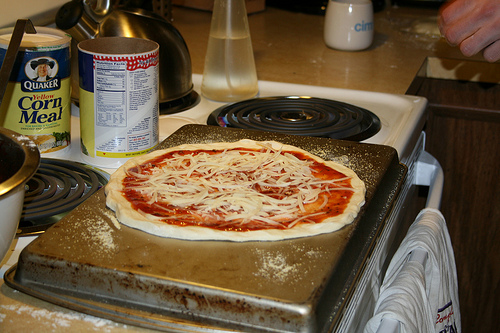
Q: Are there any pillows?
A: No, there are no pillows.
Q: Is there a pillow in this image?
A: No, there are no pillows.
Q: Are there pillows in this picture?
A: No, there are no pillows.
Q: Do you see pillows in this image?
A: No, there are no pillows.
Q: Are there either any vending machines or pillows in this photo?
A: No, there are no pillows or vending machines.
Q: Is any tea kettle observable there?
A: Yes, there is a tea kettle.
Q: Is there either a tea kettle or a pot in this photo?
A: Yes, there is a tea kettle.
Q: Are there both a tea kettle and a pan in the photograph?
A: Yes, there are both a tea kettle and a pan.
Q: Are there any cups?
A: No, there are no cups.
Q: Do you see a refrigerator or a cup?
A: No, there are no cups or refrigerators.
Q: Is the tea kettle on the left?
A: Yes, the tea kettle is on the left of the image.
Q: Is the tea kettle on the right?
A: No, the tea kettle is on the left of the image.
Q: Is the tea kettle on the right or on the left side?
A: The tea kettle is on the left of the image.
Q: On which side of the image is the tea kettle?
A: The tea kettle is on the left of the image.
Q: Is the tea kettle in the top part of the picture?
A: Yes, the tea kettle is in the top of the image.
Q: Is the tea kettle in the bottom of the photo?
A: No, the tea kettle is in the top of the image.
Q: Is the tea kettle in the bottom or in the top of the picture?
A: The tea kettle is in the top of the image.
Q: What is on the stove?
A: The tea kettle is on the stove.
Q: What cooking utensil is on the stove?
A: The cooking utensil is a tea kettle.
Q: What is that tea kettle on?
A: The tea kettle is on the stove.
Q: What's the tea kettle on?
A: The tea kettle is on the stove.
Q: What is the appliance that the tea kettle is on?
A: The appliance is a stove.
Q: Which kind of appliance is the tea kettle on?
A: The tea kettle is on the stove.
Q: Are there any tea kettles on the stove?
A: Yes, there is a tea kettle on the stove.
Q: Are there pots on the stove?
A: No, there is a tea kettle on the stove.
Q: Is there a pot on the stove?
A: No, there is a tea kettle on the stove.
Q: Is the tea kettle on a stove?
A: Yes, the tea kettle is on a stove.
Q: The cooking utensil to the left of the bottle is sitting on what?
A: The tea kettle is sitting on the stove top.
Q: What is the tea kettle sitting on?
A: The tea kettle is sitting on the stove top.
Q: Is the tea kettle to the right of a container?
A: Yes, the tea kettle is to the right of a container.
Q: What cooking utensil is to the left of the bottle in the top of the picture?
A: The cooking utensil is a tea kettle.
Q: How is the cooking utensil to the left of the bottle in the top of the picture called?
A: The cooking utensil is a tea kettle.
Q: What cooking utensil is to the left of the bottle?
A: The cooking utensil is a tea kettle.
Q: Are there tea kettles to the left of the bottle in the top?
A: Yes, there is a tea kettle to the left of the bottle.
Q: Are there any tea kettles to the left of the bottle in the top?
A: Yes, there is a tea kettle to the left of the bottle.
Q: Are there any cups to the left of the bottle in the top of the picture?
A: No, there is a tea kettle to the left of the bottle.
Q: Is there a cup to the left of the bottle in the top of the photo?
A: No, there is a tea kettle to the left of the bottle.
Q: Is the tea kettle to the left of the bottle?
A: Yes, the tea kettle is to the left of the bottle.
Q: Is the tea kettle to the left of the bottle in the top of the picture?
A: Yes, the tea kettle is to the left of the bottle.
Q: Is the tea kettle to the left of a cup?
A: No, the tea kettle is to the left of the bottle.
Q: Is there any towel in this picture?
A: Yes, there is a towel.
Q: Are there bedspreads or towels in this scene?
A: Yes, there is a towel.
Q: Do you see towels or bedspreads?
A: Yes, there is a towel.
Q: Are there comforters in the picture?
A: No, there are no comforters.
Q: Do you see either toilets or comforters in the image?
A: No, there are no comforters or toilets.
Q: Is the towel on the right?
A: Yes, the towel is on the right of the image.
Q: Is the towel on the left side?
A: No, the towel is on the right of the image.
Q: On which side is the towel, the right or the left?
A: The towel is on the right of the image.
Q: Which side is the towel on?
A: The towel is on the right of the image.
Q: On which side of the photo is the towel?
A: The towel is on the right of the image.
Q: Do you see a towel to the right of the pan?
A: Yes, there is a towel to the right of the pan.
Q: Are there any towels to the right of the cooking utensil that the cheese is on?
A: Yes, there is a towel to the right of the pan.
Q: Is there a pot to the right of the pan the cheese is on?
A: No, there is a towel to the right of the pan.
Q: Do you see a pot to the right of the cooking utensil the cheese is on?
A: No, there is a towel to the right of the pan.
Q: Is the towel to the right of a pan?
A: Yes, the towel is to the right of a pan.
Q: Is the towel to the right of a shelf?
A: No, the towel is to the right of a pan.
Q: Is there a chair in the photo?
A: No, there are no chairs.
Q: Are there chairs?
A: No, there are no chairs.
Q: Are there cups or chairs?
A: No, there are no chairs or cups.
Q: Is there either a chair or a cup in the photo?
A: No, there are no chairs or cups.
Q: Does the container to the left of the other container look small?
A: Yes, the container is small.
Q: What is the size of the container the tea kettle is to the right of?
A: The container is small.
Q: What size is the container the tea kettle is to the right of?
A: The container is small.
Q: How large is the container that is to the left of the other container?
A: The container is small.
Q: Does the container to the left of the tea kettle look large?
A: No, the container is small.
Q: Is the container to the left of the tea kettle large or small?
A: The container is small.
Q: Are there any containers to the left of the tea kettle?
A: Yes, there is a container to the left of the tea kettle.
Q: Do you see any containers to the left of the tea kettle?
A: Yes, there is a container to the left of the tea kettle.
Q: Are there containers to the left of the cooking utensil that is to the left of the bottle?
A: Yes, there is a container to the left of the tea kettle.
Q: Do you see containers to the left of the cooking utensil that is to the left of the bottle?
A: Yes, there is a container to the left of the tea kettle.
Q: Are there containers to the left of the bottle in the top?
A: Yes, there is a container to the left of the bottle.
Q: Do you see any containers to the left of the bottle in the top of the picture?
A: Yes, there is a container to the left of the bottle.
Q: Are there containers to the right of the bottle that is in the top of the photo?
A: No, the container is to the left of the bottle.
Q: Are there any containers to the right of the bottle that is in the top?
A: No, the container is to the left of the bottle.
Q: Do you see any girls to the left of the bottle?
A: No, there is a container to the left of the bottle.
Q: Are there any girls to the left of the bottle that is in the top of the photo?
A: No, there is a container to the left of the bottle.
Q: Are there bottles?
A: Yes, there is a bottle.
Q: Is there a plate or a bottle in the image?
A: Yes, there is a bottle.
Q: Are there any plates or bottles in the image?
A: Yes, there is a bottle.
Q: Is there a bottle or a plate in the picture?
A: Yes, there is a bottle.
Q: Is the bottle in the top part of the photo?
A: Yes, the bottle is in the top of the image.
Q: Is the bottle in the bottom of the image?
A: No, the bottle is in the top of the image.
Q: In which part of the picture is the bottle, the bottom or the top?
A: The bottle is in the top of the image.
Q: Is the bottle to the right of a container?
A: Yes, the bottle is to the right of a container.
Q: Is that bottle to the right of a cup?
A: No, the bottle is to the right of a container.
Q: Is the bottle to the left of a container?
A: No, the bottle is to the right of a container.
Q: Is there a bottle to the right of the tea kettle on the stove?
A: Yes, there is a bottle to the right of the tea kettle.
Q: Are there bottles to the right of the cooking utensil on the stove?
A: Yes, there is a bottle to the right of the tea kettle.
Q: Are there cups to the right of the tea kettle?
A: No, there is a bottle to the right of the tea kettle.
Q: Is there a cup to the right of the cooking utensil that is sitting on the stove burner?
A: No, there is a bottle to the right of the tea kettle.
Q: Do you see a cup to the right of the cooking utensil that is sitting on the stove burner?
A: No, there is a bottle to the right of the tea kettle.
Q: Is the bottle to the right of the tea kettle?
A: Yes, the bottle is to the right of the tea kettle.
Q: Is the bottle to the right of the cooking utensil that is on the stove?
A: Yes, the bottle is to the right of the tea kettle.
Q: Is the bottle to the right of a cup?
A: No, the bottle is to the right of the tea kettle.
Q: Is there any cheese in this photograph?
A: Yes, there is cheese.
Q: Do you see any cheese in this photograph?
A: Yes, there is cheese.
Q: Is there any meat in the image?
A: No, there is no meat.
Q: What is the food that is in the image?
A: The food is cheese.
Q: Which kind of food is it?
A: The food is cheese.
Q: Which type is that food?
A: This is cheese.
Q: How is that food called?
A: This is cheese.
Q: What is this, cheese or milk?
A: This is cheese.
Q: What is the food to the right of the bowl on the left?
A: The food is cheese.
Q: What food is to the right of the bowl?
A: The food is cheese.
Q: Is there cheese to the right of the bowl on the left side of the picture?
A: Yes, there is cheese to the right of the bowl.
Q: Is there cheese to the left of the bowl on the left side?
A: No, the cheese is to the right of the bowl.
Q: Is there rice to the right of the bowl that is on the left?
A: No, there is cheese to the right of the bowl.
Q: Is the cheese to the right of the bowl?
A: Yes, the cheese is to the right of the bowl.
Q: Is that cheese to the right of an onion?
A: No, the cheese is to the right of the bowl.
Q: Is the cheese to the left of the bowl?
A: No, the cheese is to the right of the bowl.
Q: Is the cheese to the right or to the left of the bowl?
A: The cheese is to the right of the bowl.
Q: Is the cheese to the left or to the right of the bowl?
A: The cheese is to the right of the bowl.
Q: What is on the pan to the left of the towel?
A: The cheese is on the pan.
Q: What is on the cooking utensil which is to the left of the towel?
A: The cheese is on the pan.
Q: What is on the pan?
A: The cheese is on the pan.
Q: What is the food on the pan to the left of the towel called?
A: The food is cheese.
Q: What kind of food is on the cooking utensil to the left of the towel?
A: The food is cheese.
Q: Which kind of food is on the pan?
A: The food is cheese.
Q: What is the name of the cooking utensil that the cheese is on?
A: The cooking utensil is a pan.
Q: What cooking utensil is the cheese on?
A: The cheese is on the pan.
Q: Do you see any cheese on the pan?
A: Yes, there is cheese on the pan.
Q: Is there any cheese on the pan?
A: Yes, there is cheese on the pan.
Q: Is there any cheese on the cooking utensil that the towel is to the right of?
A: Yes, there is cheese on the pan.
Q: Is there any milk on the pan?
A: No, there is cheese on the pan.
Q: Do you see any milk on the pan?
A: No, there is cheese on the pan.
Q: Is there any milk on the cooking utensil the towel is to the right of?
A: No, there is cheese on the pan.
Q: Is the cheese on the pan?
A: Yes, the cheese is on the pan.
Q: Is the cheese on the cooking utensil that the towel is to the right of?
A: Yes, the cheese is on the pan.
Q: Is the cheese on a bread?
A: No, the cheese is on the pan.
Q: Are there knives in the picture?
A: No, there are no knives.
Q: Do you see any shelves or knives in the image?
A: No, there are no knives or shelves.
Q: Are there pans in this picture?
A: Yes, there is a pan.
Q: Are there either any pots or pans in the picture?
A: Yes, there is a pan.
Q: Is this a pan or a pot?
A: This is a pan.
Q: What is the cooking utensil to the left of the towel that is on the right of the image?
A: The cooking utensil is a pan.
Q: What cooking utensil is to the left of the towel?
A: The cooking utensil is a pan.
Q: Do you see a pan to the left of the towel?
A: Yes, there is a pan to the left of the towel.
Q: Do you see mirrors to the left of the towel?
A: No, there is a pan to the left of the towel.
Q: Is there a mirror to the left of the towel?
A: No, there is a pan to the left of the towel.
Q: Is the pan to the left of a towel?
A: Yes, the pan is to the left of a towel.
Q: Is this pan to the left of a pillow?
A: No, the pan is to the left of a towel.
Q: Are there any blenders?
A: No, there are no blenders.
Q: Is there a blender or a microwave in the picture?
A: No, there are no blenders or microwaves.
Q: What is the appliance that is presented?
A: The appliance is a stove.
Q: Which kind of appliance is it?
A: The appliance is a stove.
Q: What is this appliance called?
A: This is a stove.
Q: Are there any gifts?
A: No, there are no gifts.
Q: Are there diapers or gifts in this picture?
A: No, there are no gifts or diapers.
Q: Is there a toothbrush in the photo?
A: No, there are no toothbrushes.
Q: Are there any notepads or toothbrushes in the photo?
A: No, there are no toothbrushes or notepads.